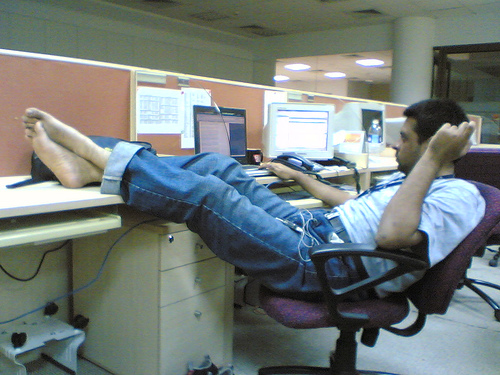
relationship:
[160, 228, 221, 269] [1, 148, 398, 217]
drawer under table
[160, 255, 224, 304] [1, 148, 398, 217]
drawer under table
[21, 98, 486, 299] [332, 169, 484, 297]
man has shirt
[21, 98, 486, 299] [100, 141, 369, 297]
man wearing jeans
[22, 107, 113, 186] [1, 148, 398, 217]
foot on desk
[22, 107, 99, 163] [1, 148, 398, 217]
foot on desk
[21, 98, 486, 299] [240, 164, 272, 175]
man typing on keyboard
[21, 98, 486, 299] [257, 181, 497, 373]
man has chair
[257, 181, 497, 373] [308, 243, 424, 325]
chair has armrest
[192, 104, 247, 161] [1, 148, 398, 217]
monitor on desk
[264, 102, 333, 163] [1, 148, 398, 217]
monitor on desk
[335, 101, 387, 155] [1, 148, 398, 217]
monitor on desk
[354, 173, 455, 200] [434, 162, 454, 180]
lanyard around neck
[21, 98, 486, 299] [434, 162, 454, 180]
man has neck